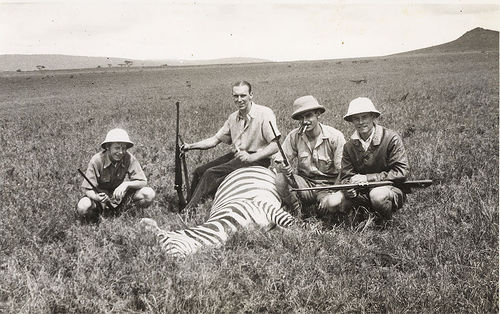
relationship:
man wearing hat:
[317, 96, 409, 225] [336, 99, 379, 118]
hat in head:
[336, 99, 379, 118] [340, 96, 387, 118]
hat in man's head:
[288, 91, 324, 114] [297, 106, 319, 131]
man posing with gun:
[73, 127, 155, 222] [267, 118, 287, 161]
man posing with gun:
[317, 96, 409, 225] [293, 180, 392, 187]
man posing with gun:
[221, 78, 280, 168] [175, 97, 190, 207]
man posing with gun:
[268, 94, 346, 219] [77, 166, 103, 192]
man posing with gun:
[317, 96, 409, 225] [284, 176, 437, 197]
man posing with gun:
[268, 94, 346, 219] [264, 114, 304, 216]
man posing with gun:
[174, 78, 286, 214] [171, 99, 187, 208]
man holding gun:
[73, 127, 155, 222] [149, 68, 210, 211]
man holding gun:
[320, 98, 409, 220] [289, 179, 433, 192]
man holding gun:
[317, 96, 409, 225] [288, 175, 432, 196]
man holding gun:
[279, 92, 345, 219] [264, 115, 309, 218]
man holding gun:
[174, 78, 286, 214] [173, 97, 187, 213]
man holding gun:
[73, 121, 154, 232] [73, 165, 133, 230]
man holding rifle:
[174, 78, 286, 214] [170, 98, 194, 212]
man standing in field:
[73, 127, 155, 222] [0, 45, 499, 312]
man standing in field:
[174, 78, 286, 214] [0, 45, 499, 312]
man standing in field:
[317, 96, 409, 225] [16, 57, 481, 272]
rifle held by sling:
[173, 98, 193, 208] [179, 134, 192, 206]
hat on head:
[96, 128, 142, 152] [88, 120, 145, 167]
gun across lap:
[296, 163, 439, 185] [321, 186, 402, 196]